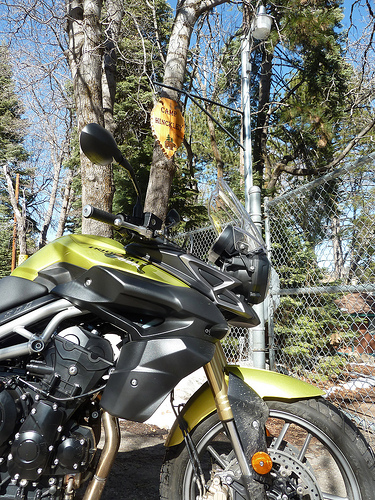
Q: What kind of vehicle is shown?
A: Motorcycle.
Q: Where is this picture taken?
A: Camp Hinckley.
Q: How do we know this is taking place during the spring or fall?
A: No leaves on trees.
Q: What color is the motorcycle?
A: Green.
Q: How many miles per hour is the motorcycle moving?
A: 0.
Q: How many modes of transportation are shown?
A: 1.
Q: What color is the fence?
A: Silver.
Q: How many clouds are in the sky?
A: 0.